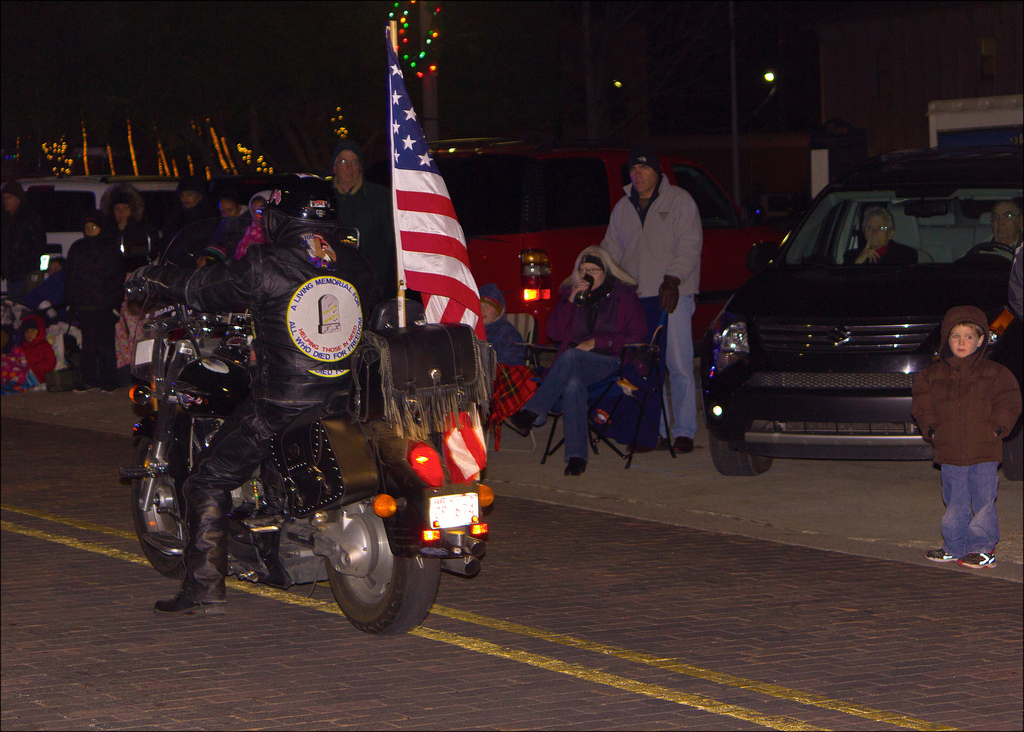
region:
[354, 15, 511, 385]
the American flag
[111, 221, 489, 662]
man riding a bike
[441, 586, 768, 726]
two yellow lines on the road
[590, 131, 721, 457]
man wears a winter jacket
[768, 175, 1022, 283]
two people inside a car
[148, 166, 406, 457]
motorcyclist wearing a black jacket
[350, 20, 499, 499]
a large United States flag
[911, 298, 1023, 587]
a child in brown coat and blue jeans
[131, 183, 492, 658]
a man wearing black leather jacket and pants on motorcycle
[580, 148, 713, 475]
a man in light blue jeans and cream jacket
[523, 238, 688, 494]
woman wearing blue jeans and purple jacket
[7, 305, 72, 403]
a child wearing a red hooded jacket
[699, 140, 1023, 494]
a black car with 2 people in front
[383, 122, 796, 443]
a large red SUV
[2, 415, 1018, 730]
a road with yellow lines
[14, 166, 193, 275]
a large white vehicle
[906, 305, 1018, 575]
child wearing brown coat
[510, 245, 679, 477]
woman sitting in foldable chair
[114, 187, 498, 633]
man riding motorcycle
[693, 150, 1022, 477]
elderly man sitting in car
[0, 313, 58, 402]
child wearing red coat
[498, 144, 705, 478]
man standing behind seated woman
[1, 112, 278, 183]
assortment of christmas lights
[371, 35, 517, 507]
large american flag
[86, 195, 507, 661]
black motorcycle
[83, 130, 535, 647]
man wearing black leather jacket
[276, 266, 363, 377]
white circle on back of black leather jacket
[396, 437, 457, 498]
red motorcycle tail light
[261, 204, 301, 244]
person has a headperson has a head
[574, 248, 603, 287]
person has a head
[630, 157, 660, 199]
person has a head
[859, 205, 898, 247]
person has a head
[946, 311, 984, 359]
person has a head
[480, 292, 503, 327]
person has a head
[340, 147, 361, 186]
person has a head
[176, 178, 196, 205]
person has a head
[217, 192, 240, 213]
person has a head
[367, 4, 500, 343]
A red, white and blue American flag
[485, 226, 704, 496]
A person sitting in a chair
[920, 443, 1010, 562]
A pair of blue jeans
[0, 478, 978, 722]
Yellow lines on the road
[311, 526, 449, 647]
A round rubber tire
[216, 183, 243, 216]
person has a head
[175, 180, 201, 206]
person has a head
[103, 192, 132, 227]
person has a head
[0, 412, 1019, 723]
clear black colored street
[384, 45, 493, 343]
american flag on the motorcycle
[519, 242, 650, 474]
woman in purple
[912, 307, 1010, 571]
little boy wearing a brown jacket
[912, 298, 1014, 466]
brown colored jacket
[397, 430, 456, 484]
red colored light on motorcycle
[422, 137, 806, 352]
red colored suv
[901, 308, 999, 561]
A person who is outside.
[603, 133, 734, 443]
A person who is outside.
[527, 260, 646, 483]
A person who is outside.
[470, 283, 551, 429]
A person who is outside.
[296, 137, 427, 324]
A person who is outside.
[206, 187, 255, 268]
A person who is outside.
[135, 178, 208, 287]
A person who is outside.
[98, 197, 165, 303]
A person who is outside.